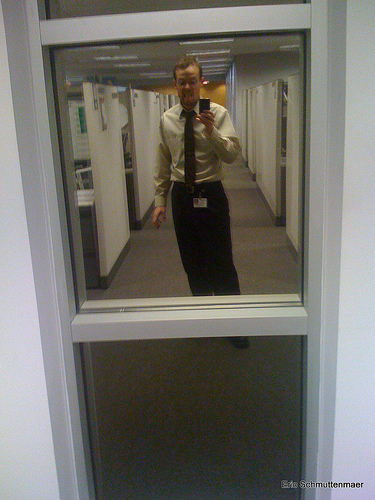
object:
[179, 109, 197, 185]
necktie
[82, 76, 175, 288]
wall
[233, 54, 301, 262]
wall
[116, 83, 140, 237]
cubicle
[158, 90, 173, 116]
cubicle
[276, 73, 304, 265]
cubicle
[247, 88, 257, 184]
cubicle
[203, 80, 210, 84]
sign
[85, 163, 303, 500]
hallway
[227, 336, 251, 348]
shoe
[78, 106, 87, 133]
blue paper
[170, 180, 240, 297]
pants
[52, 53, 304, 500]
office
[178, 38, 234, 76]
lighting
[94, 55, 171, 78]
lighting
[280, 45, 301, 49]
lighting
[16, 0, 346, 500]
frame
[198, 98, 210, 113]
cell phone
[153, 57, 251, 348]
male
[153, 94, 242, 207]
shirt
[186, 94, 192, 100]
tongue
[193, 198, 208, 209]
identification badge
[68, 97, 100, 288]
cubicle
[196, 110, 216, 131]
hand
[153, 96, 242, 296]
clothes